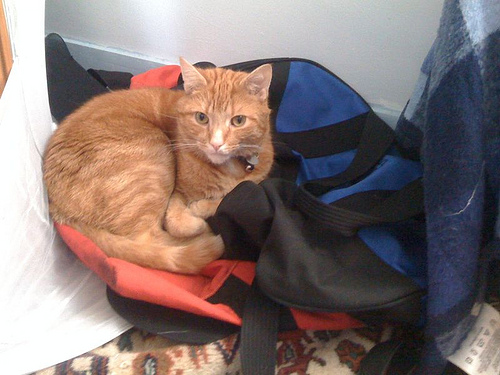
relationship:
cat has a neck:
[41, 56, 274, 279] [183, 141, 267, 169]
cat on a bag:
[41, 56, 274, 279] [219, 58, 427, 336]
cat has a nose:
[41, 56, 274, 279] [212, 134, 224, 147]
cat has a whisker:
[41, 56, 274, 279] [235, 143, 286, 179]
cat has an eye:
[41, 56, 274, 279] [233, 116, 246, 126]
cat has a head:
[41, 56, 274, 279] [176, 66, 272, 165]